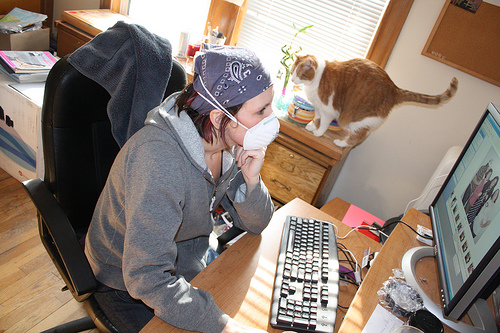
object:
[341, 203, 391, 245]
paper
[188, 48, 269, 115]
bandana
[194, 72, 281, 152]
mask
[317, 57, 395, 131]
body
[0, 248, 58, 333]
ground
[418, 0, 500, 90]
board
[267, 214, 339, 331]
computer keyborad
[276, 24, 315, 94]
lucky bamboo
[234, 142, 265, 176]
hand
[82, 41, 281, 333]
person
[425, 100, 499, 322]
monitor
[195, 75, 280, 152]
face mask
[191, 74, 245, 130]
strap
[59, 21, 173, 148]
towel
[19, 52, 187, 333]
chair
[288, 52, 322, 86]
head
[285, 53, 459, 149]
cat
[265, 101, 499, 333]
computer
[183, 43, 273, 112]
handkerchief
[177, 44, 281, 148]
head